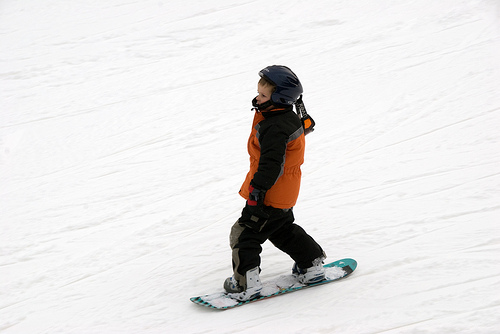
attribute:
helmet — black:
[259, 63, 303, 116]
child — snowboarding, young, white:
[229, 62, 332, 301]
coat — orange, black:
[246, 111, 302, 211]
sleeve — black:
[253, 125, 282, 192]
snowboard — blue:
[194, 253, 357, 306]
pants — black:
[232, 207, 323, 271]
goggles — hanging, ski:
[295, 98, 317, 131]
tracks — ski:
[363, 151, 439, 218]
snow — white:
[336, 26, 487, 256]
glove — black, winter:
[249, 186, 265, 202]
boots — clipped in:
[223, 262, 306, 282]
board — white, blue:
[195, 268, 342, 289]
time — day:
[6, 7, 280, 125]